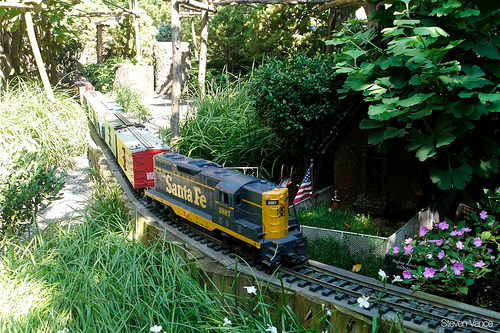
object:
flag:
[279, 160, 317, 209]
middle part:
[88, 93, 169, 186]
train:
[77, 76, 313, 269]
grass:
[33, 227, 225, 320]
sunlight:
[108, 48, 188, 128]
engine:
[144, 152, 309, 272]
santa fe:
[163, 174, 209, 208]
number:
[227, 209, 232, 219]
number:
[223, 208, 228, 215]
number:
[220, 205, 222, 216]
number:
[216, 207, 220, 214]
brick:
[290, 290, 327, 331]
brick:
[326, 299, 375, 331]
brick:
[208, 260, 253, 328]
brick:
[249, 279, 295, 326]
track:
[85, 116, 485, 330]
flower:
[400, 266, 412, 279]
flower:
[420, 265, 437, 278]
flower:
[390, 244, 400, 254]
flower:
[401, 242, 413, 255]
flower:
[432, 238, 443, 247]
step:
[260, 259, 270, 267]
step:
[264, 240, 281, 264]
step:
[267, 245, 278, 252]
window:
[221, 191, 230, 202]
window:
[214, 190, 223, 202]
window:
[231, 192, 241, 203]